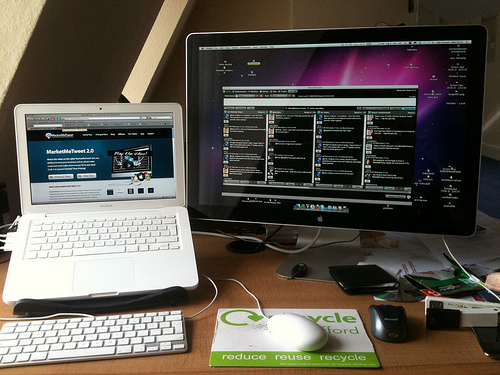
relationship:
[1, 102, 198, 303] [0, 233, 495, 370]
laptop on a desk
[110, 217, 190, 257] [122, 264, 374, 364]
keyboard on a desk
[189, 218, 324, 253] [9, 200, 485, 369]
cords on a desk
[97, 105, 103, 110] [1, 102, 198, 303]
camera lens on laptop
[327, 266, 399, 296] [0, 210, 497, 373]
wallet on table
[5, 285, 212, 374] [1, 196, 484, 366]
keyboard on table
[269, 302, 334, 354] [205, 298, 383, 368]
mouse on mousepad